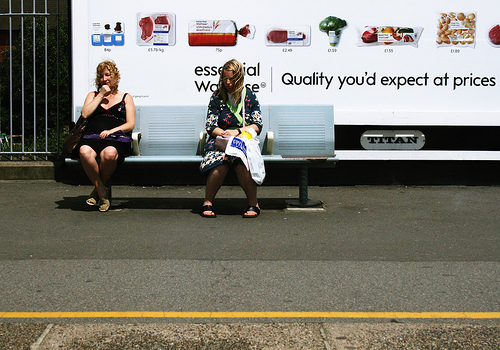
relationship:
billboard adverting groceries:
[91, 12, 500, 94] [86, 2, 480, 56]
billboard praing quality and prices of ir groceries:
[83, 1, 483, 104] [91, 12, 500, 54]